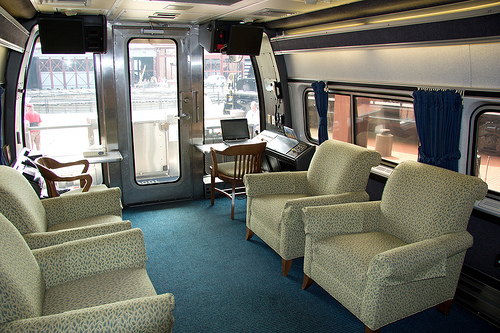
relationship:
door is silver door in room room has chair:
[111, 26, 194, 200] [1, 0, 500, 331]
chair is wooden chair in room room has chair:
[210, 143, 269, 218] [1, 139, 479, 332]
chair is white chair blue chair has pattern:
[1, 139, 479, 332] [0, 141, 499, 333]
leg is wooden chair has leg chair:
[229, 179, 235, 221] [202, 136, 265, 221]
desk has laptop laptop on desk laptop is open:
[196, 119, 267, 173] [220, 119, 261, 146]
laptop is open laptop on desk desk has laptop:
[220, 119, 261, 146] [196, 119, 267, 173]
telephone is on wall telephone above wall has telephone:
[271, 81, 282, 128] [256, 70, 282, 130]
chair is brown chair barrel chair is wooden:
[210, 143, 269, 218] [210, 143, 269, 218]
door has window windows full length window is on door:
[111, 26, 194, 200] [127, 37, 181, 186]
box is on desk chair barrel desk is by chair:
[82, 147, 108, 157] [32, 147, 124, 191]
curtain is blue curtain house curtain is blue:
[412, 86, 463, 174] [310, 80, 328, 146]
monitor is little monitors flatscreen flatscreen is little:
[36, 17, 84, 54] [227, 14, 263, 56]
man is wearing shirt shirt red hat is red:
[22, 105, 42, 151] [25, 104, 34, 108]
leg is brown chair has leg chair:
[229, 179, 235, 221] [202, 136, 265, 221]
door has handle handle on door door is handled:
[172, 112, 190, 121] [176, 113, 192, 118]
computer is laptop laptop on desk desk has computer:
[220, 119, 261, 146] [196, 119, 267, 173]